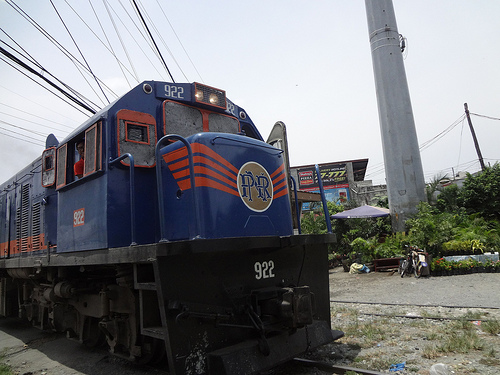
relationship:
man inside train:
[71, 141, 85, 179] [1, 72, 354, 373]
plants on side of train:
[340, 190, 499, 267] [4, 114, 338, 343]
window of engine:
[57, 131, 93, 181] [5, 77, 333, 364]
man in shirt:
[71, 137, 84, 177] [72, 158, 84, 176]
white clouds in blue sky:
[86, 50, 146, 106] [188, 10, 315, 78]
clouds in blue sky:
[257, 26, 327, 73] [0, 0, 500, 187]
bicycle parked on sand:
[396, 242, 426, 283] [325, 267, 499, 371]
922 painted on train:
[240, 254, 290, 287] [23, 67, 383, 358]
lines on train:
[162, 141, 297, 203] [1, 72, 354, 373]